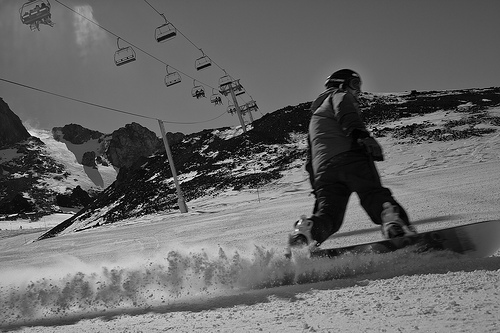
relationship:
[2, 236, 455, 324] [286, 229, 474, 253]
snow behind snowboard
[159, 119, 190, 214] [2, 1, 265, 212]
pole supports lift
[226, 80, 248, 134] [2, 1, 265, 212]
pole supports lift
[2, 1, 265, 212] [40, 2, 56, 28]
lift carries person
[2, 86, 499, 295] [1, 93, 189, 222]
snow on mountain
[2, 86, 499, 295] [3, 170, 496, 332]
snow covers ground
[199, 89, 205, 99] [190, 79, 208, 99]
person on chair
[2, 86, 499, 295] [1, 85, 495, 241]
snow covers mountain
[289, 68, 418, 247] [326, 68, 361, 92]
person wears helmet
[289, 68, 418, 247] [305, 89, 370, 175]
person wears jacket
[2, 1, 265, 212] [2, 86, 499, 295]
lift over snow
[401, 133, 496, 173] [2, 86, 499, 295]
tracks in snow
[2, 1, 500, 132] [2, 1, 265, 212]
sky above lift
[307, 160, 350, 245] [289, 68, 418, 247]
leg of man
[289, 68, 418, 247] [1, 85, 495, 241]
person on mountain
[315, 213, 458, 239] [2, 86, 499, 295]
shadow on snow